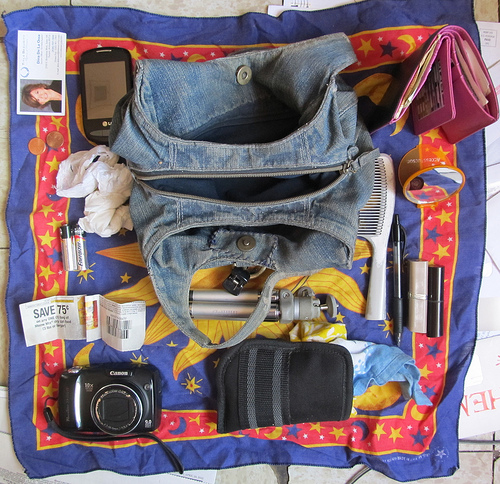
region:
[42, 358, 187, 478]
small black camera with a lanyard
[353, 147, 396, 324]
a white comb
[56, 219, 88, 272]
two AA batteries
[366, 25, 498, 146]
a pink wallet standing on its side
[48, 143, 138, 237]
a crumpled up tissue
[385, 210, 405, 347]
a black pen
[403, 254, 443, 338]
two tubes of lipstick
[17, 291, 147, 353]
a 75 cents off coupon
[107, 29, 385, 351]
a denim purse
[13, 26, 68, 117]
a business card with a headshot on it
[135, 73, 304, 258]
denim purse on bandanna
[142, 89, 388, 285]
denim purse is blue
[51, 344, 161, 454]
black point and shoot camera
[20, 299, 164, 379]
coupon is above camera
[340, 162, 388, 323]
grey comb next to purse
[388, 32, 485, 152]
pink wallet on bandanna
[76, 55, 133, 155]
black phone under purse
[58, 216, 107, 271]
two batteries on bandanna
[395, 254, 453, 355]
tubes of lipstick and mascara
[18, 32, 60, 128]
license card on bandanna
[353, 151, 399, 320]
A comb is white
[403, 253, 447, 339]
Two tubes of lipstick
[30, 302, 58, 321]
The word "SAVE" on a coupon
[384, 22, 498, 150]
The open wallet is pink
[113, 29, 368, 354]
A blue jean bag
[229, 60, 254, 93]
A button on a blue jean bag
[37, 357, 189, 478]
The camera is black and has a round lense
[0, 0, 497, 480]
Many items on a blue blanket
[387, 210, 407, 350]
The pen is black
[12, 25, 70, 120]
A rectangular identification card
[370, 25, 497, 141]
Pink wallet on cloth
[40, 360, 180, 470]
Black Canon brand Camera on cloth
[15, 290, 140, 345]
Coupon for 75 cents on cloth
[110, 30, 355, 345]
Denim hand bag on cloth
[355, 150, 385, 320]
Silver plastic comb on cloth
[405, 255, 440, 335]
Two tubes of lipstick on cloth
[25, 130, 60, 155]
Two copper pennies on cloth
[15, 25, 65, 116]
Photo ID card on cloth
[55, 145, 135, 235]
Used wadded tissue on cloth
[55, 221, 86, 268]
Two AA batteries on cloth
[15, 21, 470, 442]
blanket full of stuff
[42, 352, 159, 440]
black cannon camera with strap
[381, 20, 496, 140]
pink wallet on the blanket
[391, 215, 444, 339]
two lipsticks next to a pen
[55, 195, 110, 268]
two batteries below tissue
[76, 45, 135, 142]
black LG cell phone by the purse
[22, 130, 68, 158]
two pennies on the blanket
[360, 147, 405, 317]
white comb near the pen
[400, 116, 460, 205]
orange mirror below wallet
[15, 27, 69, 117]
business card by the cell phone